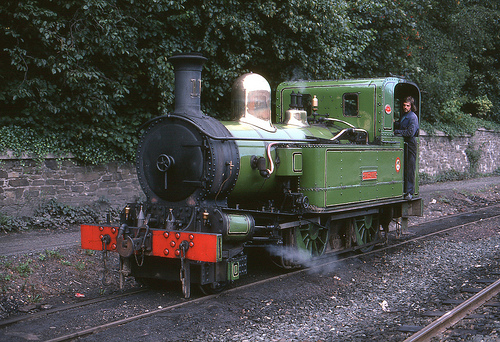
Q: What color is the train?
A: Green.